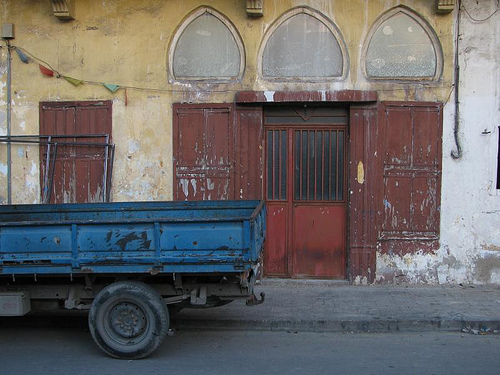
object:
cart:
[1, 201, 266, 361]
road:
[0, 316, 499, 374]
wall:
[0, 0, 499, 290]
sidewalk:
[212, 277, 500, 329]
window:
[358, 2, 445, 86]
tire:
[86, 278, 169, 359]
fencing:
[0, 133, 109, 201]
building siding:
[0, 91, 169, 189]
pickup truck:
[2, 199, 270, 361]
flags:
[8, 45, 122, 94]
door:
[262, 105, 351, 283]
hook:
[451, 0, 463, 159]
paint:
[0, 0, 498, 293]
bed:
[0, 200, 266, 275]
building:
[2, 0, 484, 290]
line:
[11, 45, 455, 93]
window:
[163, 4, 245, 81]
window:
[257, 6, 352, 85]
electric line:
[448, 0, 462, 159]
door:
[37, 101, 113, 204]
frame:
[0, 131, 116, 203]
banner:
[2, 35, 242, 95]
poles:
[0, 132, 116, 203]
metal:
[1, 199, 270, 278]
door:
[367, 101, 441, 285]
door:
[172, 101, 237, 199]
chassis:
[0, 272, 267, 318]